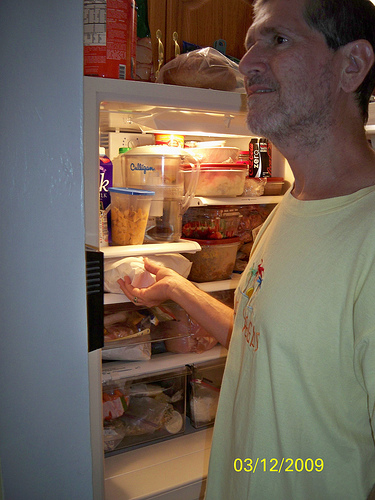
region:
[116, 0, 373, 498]
man putting food in the refrigerator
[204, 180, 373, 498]
white tee shirt man is wearing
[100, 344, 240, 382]
shelf of the refrigerator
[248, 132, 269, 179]
black, red and white can of soda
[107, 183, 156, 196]
blue top for plastic container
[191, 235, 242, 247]
red top of bowel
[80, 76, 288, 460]
refrigerator full of food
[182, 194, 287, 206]
top shelf of the refrigerator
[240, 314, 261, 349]
red design on front of tee shirt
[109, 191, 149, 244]
plastic container with food in it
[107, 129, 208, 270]
Culligan container in the refrigerator.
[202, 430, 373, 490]
Date on the photo.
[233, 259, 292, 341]
Logo on the shirt.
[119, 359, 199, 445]
Drawer in the fridge.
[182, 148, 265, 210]
Container in the fridge.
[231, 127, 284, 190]
Coke in the fridge.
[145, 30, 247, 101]
Bread on the fridge.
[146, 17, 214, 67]
Handles on the cabinet.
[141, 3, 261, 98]
Wood cabinet with handles.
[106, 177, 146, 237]
Container with blue lid.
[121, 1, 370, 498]
a man with brown eyes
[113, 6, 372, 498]
a man with facial hair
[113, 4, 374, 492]
a man wearing a yellow shirt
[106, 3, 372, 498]
a man getting food out of the refridgerator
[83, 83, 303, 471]
an open refridgerator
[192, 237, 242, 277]
a container with a red lid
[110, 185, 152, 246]
a container with a blue lid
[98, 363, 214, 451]
a drawer full of food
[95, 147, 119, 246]
a container of silk milk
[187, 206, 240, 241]
a package of strawberries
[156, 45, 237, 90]
a loaf of bread in a plastic bag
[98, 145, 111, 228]
a container of silk milk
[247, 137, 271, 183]
a can of coca cola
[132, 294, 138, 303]
a man has a ring on his finger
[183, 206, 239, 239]
a plastic container of strawberries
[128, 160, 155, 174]
a brand name logo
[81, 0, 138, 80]
a container of protein powder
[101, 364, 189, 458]
the refrigerator crisper drawer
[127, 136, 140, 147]
the temperature control thermostat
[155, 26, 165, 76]
gold color kitchen cabinet handles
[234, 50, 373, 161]
the face of an ill shaved man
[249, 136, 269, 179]
a can of coke zero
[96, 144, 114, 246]
a carton of soy milk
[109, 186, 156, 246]
a plastic container of left-overs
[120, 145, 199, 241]
a pitcher with a brand name on it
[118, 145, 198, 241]
a pitcher that says Culligan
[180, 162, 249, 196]
leftovers in a plastic container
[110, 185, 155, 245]
plastic container in a blue lid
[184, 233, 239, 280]
plastic container with a red lid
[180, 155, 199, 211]
the handle of a pitcher